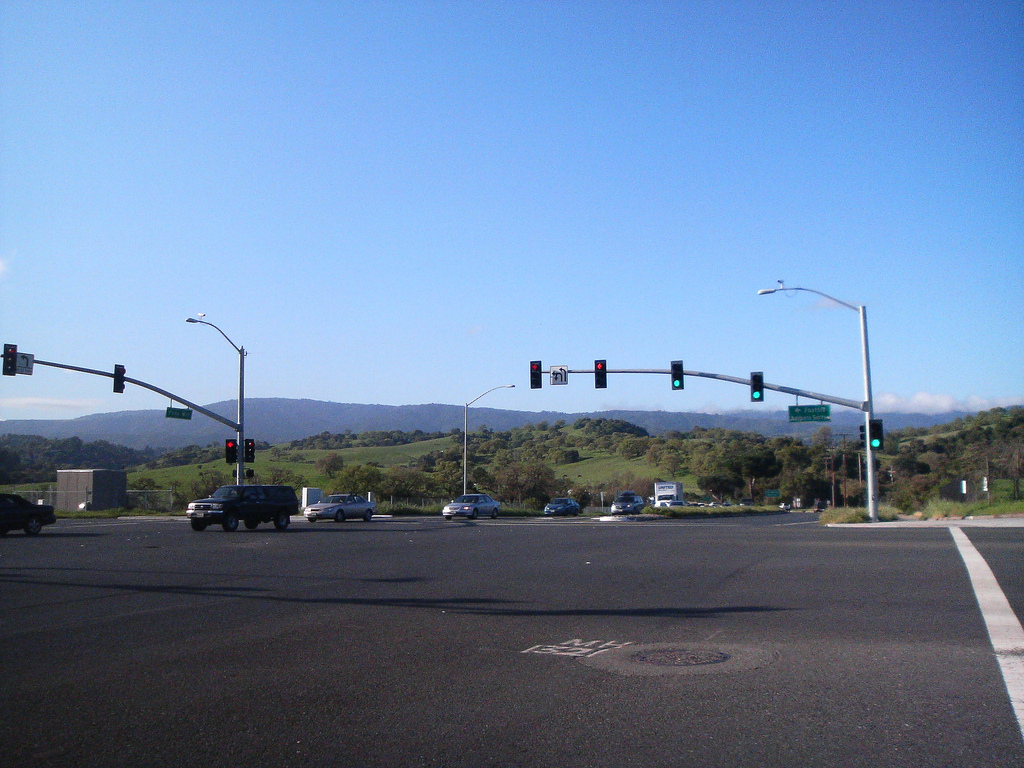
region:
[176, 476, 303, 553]
moving black vehicle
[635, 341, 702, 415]
green signal light on post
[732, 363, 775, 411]
green signal light on post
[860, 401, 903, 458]
green signal light on post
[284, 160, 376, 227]
blue sky with no clouds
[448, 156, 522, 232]
blue sky with no clouds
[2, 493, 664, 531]
card driving down road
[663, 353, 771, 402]
traffic lights are green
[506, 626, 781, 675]
white marking near manhole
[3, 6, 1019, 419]
sky is clear and blue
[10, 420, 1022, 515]
hills covered with trees and grass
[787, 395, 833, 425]
street sign is green and white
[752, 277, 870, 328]
street light on top of tall pole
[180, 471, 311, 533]
a car on a street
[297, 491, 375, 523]
a car on a street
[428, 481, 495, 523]
a car on a street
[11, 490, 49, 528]
a car on a street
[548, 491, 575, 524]
a car on a street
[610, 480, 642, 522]
a car on a street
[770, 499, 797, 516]
a car on a street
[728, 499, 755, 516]
a car on a street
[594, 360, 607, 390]
A traffic signal that is currently red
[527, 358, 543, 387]
A traffic signal that is currently red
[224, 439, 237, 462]
A traffic signal that is currently red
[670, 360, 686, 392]
A traffic signal that is currently green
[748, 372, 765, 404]
A traffic signal that is currently green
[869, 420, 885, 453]
A traffic signal that is currently green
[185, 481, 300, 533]
A black SUV driving down the road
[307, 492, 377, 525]
A silver car driving down the road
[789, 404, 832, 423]
A green and white street sign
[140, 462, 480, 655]
The truck is driving down the road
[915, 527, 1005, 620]
wide white line on street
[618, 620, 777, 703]
grate in middle of street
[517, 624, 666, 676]
white words on the street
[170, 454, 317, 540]
black van riding down the street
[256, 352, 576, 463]
tall mountain range in the distance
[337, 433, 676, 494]
tree covered green hills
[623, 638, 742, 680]
iron manhole access circled by rough concrete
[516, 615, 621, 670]
MH 1321 etched with white spray paint into the asphalt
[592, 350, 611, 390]
traffic control light displaying red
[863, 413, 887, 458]
green traffic control light hanging on metal pole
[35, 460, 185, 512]
small brown building surrounded by chain link fence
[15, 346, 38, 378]
white square sign with black left arrow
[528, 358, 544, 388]
the traffic light hanging on the pole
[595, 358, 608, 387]
the traffic light hanging on the pole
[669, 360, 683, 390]
the traffic light hanging on the pole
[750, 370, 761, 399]
the traffic light hanging on the pole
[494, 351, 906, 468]
set of traffic lights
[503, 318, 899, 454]
set of traffic lights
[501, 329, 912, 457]
set of traffic lights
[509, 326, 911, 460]
set of traffic lights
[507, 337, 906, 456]
set of traffic lights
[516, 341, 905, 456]
set of traffic lights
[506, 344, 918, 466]
set of traffic lights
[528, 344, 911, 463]
set of traffic lights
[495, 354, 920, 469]
set of traffic lights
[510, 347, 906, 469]
set of traffic lights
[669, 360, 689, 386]
traffic light on pole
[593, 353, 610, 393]
traffic light on pole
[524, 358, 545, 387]
traffic light on pole